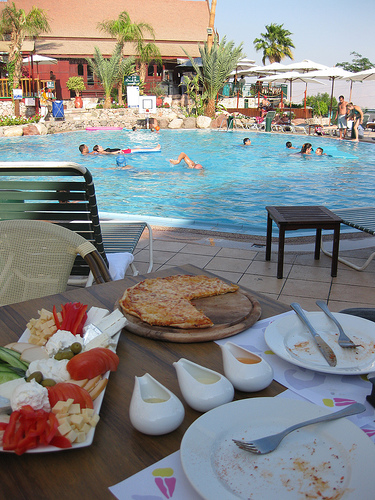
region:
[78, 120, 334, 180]
Guests enjoying the pool.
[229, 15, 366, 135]
Palm trees and umbrellas offer shade for guests.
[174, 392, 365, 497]
An empty plate is the greatest compliment to a chef.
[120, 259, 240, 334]
A pizza waiting to be eaten.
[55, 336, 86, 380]
Cottage cheese, olives and tomato.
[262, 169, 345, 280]
An empty table by the pool.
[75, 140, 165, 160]
Floating in the pool with a companion.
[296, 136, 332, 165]
Mother teaching child to swim.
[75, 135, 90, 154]
head of a person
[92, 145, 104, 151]
head of a person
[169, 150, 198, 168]
arm of a person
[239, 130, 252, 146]
head of a person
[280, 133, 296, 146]
head of a person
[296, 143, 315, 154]
head of a person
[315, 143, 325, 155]
head of a person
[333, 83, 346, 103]
head of a person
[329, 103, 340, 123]
arm of a person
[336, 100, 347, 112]
body of a person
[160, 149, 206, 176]
man swimming in the water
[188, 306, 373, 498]
two dirty white plates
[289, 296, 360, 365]
fork and knife on dirty white plate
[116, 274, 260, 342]
pizza on a wooden slab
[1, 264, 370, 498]
table plates and food are on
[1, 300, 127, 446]
white vegetable platter on the table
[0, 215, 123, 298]
chair at the table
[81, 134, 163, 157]
two people floating together in the water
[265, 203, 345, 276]
wood table beside the pool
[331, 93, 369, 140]
pool standing on the pool's edge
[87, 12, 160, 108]
palm trees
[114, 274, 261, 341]
cheese pizza on wooden serving platter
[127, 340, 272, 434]
ceramic pouring sauce dishes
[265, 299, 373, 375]
dirty plate with silverware indicating person is finished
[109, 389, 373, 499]
placemat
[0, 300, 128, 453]
plate of appetizers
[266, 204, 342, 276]
square wooden table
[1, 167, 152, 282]
metal and plastic chaise lounge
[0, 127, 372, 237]
people enjoying pool on a sunny day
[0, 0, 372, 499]
pool at large resort hotel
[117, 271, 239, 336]
pizza on top of a wooden cutting board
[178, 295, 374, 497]
dirty empty plates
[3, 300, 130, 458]
a full plate of various appetizers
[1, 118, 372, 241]
a pool full of people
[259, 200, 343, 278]
a small brown wooden table next to the pool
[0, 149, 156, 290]
a dark green and white lounge chair next to the pool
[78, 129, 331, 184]
people swimming in a pool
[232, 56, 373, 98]
white umbrellas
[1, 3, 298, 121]
palm trees surrounding pool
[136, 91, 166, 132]
small basketball hoop floating in the pool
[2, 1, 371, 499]
Tropical resort, showing pool, lounging area, edibles and people.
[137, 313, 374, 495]
Empty plates, placemats, forks and tureens.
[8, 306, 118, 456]
Platter with cut up edibles.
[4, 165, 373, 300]
Chairs and table on tile deck, at poolside.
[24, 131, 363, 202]
Blue pool with patrons, swimming and recreating.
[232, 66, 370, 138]
White umbrellas and people, near poolside.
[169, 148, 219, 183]
a person swimming in a pool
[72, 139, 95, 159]
a person swimming in a pool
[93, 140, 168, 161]
a person swimming in a pool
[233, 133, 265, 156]
a person swimming in a pool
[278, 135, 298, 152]
a person swimming in a pool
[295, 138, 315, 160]
a person swimming in a pool